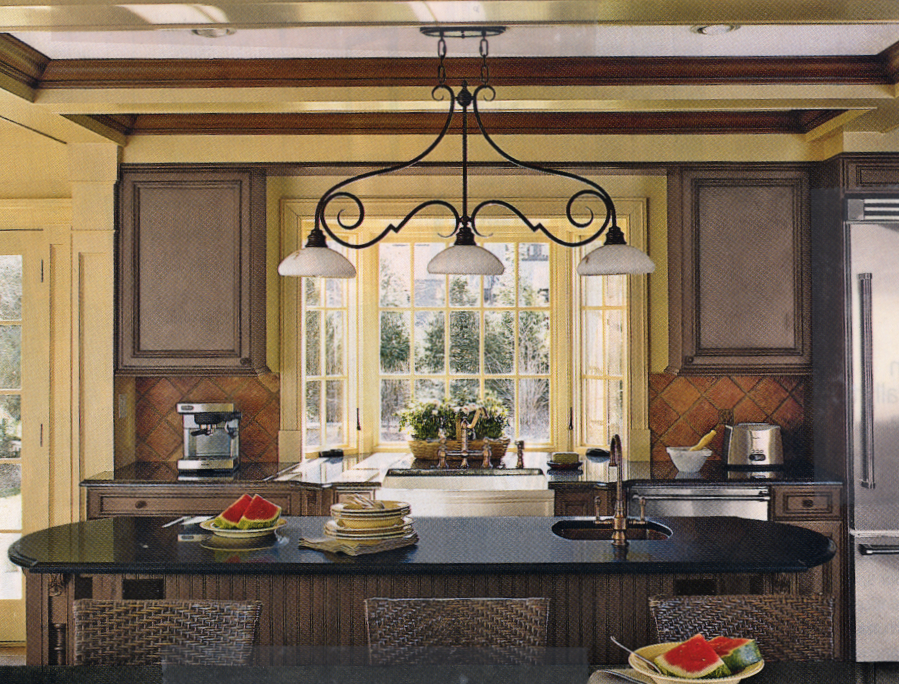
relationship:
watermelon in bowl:
[654, 626, 761, 681] [620, 621, 767, 680]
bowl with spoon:
[620, 621, 767, 680] [605, 625, 644, 653]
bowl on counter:
[663, 445, 715, 475] [572, 456, 846, 497]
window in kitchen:
[290, 206, 632, 469] [0, 2, 892, 681]